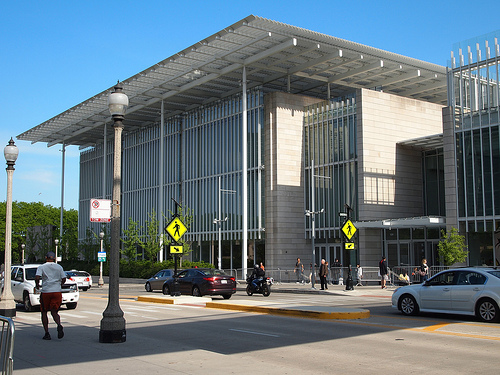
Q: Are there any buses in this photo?
A: No, there are no buses.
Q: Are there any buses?
A: No, there are no buses.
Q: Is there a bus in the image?
A: No, there are no buses.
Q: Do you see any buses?
A: No, there are no buses.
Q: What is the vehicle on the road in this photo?
A: The vehicle is a car.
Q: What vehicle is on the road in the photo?
A: The vehicle is a car.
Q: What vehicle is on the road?
A: The vehicle is a car.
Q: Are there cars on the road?
A: Yes, there is a car on the road.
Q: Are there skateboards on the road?
A: No, there is a car on the road.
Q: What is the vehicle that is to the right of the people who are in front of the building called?
A: The vehicle is a car.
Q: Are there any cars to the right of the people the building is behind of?
A: Yes, there is a car to the right of the people.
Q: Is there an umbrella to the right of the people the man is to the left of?
A: No, there is a car to the right of the people.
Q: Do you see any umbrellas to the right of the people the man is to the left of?
A: No, there is a car to the right of the people.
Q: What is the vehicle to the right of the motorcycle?
A: The vehicle is a car.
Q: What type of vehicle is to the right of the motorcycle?
A: The vehicle is a car.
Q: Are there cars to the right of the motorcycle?
A: Yes, there is a car to the right of the motorcycle.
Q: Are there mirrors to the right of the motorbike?
A: No, there is a car to the right of the motorbike.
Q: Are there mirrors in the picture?
A: No, there are no mirrors.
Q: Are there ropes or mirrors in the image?
A: No, there are no mirrors or ropes.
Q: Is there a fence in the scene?
A: Yes, there is a fence.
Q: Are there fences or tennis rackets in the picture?
A: Yes, there is a fence.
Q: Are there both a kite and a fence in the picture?
A: No, there is a fence but no kites.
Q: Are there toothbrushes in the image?
A: No, there are no toothbrushes.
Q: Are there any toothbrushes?
A: No, there are no toothbrushes.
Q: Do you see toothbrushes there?
A: No, there are no toothbrushes.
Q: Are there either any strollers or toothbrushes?
A: No, there are no toothbrushes or strollers.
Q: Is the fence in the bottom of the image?
A: Yes, the fence is in the bottom of the image.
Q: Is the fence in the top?
A: No, the fence is in the bottom of the image.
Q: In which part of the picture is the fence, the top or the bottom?
A: The fence is in the bottom of the image.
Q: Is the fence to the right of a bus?
A: No, the fence is to the right of the car.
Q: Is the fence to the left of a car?
A: No, the fence is to the right of a car.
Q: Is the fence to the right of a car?
A: Yes, the fence is to the right of a car.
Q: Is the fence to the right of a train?
A: No, the fence is to the right of a car.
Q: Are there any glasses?
A: No, there are no glasses.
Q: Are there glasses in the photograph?
A: No, there are no glasses.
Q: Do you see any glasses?
A: No, there are no glasses.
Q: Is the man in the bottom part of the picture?
A: Yes, the man is in the bottom of the image.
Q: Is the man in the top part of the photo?
A: No, the man is in the bottom of the image.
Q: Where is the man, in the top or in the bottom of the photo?
A: The man is in the bottom of the image.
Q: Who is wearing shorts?
A: The man is wearing shorts.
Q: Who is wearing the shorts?
A: The man is wearing shorts.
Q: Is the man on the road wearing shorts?
A: Yes, the man is wearing shorts.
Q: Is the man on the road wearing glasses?
A: No, the man is wearing shorts.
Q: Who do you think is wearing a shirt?
A: The man is wearing a shirt.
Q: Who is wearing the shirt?
A: The man is wearing a shirt.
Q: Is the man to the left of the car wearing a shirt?
A: Yes, the man is wearing a shirt.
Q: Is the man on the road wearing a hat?
A: No, the man is wearing a shirt.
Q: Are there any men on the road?
A: Yes, there is a man on the road.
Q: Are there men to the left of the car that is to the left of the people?
A: Yes, there is a man to the left of the car.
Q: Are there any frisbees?
A: No, there are no frisbees.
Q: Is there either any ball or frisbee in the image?
A: No, there are no frisbees or balls.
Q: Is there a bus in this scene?
A: No, there are no buses.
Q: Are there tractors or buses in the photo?
A: No, there are no buses or tractors.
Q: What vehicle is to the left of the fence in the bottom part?
A: The vehicle is a car.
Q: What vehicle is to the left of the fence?
A: The vehicle is a car.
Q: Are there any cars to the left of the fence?
A: Yes, there is a car to the left of the fence.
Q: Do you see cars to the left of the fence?
A: Yes, there is a car to the left of the fence.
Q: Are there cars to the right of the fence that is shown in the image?
A: No, the car is to the left of the fence.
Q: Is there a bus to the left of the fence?
A: No, there is a car to the left of the fence.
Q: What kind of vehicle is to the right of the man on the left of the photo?
A: The vehicle is a car.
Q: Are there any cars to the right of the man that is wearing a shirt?
A: Yes, there is a car to the right of the man.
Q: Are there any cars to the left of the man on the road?
A: No, the car is to the right of the man.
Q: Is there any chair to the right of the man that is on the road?
A: No, there is a car to the right of the man.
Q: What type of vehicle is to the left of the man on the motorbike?
A: The vehicle is a car.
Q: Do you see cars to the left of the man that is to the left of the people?
A: Yes, there is a car to the left of the man.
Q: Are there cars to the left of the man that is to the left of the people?
A: Yes, there is a car to the left of the man.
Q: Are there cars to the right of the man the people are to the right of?
A: No, the car is to the left of the man.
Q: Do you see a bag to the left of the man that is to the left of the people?
A: No, there is a car to the left of the man.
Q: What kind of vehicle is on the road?
A: The vehicle is a car.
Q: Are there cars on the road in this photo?
A: Yes, there is a car on the road.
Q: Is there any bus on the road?
A: No, there is a car on the road.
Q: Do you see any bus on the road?
A: No, there is a car on the road.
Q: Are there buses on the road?
A: No, there is a car on the road.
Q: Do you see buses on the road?
A: No, there is a car on the road.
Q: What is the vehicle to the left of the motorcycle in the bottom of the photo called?
A: The vehicle is a car.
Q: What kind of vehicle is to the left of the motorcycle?
A: The vehicle is a car.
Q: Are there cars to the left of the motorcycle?
A: Yes, there is a car to the left of the motorcycle.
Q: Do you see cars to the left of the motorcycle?
A: Yes, there is a car to the left of the motorcycle.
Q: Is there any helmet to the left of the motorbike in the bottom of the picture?
A: No, there is a car to the left of the motorbike.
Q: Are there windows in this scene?
A: Yes, there are windows.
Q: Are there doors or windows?
A: Yes, there are windows.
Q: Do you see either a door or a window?
A: Yes, there are windows.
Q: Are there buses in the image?
A: No, there are no buses.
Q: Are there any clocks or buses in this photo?
A: No, there are no buses or clocks.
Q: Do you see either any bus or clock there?
A: No, there are no buses or clocks.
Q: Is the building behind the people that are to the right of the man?
A: Yes, the building is behind the people.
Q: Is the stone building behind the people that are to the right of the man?
A: Yes, the building is behind the people.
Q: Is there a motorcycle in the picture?
A: Yes, there is a motorcycle.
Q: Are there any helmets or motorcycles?
A: Yes, there is a motorcycle.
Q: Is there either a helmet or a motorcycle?
A: Yes, there is a motorcycle.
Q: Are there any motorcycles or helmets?
A: Yes, there is a motorcycle.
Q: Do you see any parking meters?
A: No, there are no parking meters.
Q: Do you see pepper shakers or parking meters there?
A: No, there are no parking meters or pepper shakers.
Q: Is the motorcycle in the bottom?
A: Yes, the motorcycle is in the bottom of the image.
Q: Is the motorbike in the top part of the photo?
A: No, the motorbike is in the bottom of the image.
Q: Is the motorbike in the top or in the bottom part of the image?
A: The motorbike is in the bottom of the image.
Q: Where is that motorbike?
A: The motorbike is on the road.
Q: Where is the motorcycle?
A: The motorbike is on the road.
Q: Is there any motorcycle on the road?
A: Yes, there is a motorcycle on the road.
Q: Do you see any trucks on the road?
A: No, there is a motorcycle on the road.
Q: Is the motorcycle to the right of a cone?
A: No, the motorcycle is to the right of the car.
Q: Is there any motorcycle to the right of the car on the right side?
A: No, the motorcycle is to the left of the car.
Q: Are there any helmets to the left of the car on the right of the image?
A: No, there is a motorcycle to the left of the car.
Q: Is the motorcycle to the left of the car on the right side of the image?
A: Yes, the motorcycle is to the left of the car.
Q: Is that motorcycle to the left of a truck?
A: No, the motorcycle is to the left of the car.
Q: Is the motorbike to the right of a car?
A: No, the motorbike is to the left of a car.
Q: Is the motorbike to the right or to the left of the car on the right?
A: The motorbike is to the left of the car.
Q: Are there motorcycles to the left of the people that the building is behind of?
A: Yes, there is a motorcycle to the left of the people.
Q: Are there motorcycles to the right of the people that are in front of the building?
A: No, the motorcycle is to the left of the people.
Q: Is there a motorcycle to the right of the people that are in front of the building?
A: No, the motorcycle is to the left of the people.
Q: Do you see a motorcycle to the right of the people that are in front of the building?
A: No, the motorcycle is to the left of the people.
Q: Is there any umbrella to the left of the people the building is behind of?
A: No, there is a motorcycle to the left of the people.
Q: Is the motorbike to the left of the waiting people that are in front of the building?
A: Yes, the motorbike is to the left of the people.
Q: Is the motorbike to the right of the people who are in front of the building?
A: No, the motorbike is to the left of the people.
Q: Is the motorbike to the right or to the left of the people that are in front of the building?
A: The motorbike is to the left of the people.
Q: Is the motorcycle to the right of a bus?
A: No, the motorcycle is to the right of the car.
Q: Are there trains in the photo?
A: No, there are no trains.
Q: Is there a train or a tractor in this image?
A: No, there are no trains or tractors.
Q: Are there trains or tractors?
A: No, there are no trains or tractors.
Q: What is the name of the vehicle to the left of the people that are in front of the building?
A: The vehicle is a car.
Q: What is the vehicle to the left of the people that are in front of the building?
A: The vehicle is a car.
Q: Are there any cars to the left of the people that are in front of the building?
A: Yes, there is a car to the left of the people.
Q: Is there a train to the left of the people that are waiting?
A: No, there is a car to the left of the people.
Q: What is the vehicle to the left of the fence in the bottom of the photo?
A: The vehicle is a car.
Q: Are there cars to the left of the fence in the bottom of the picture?
A: Yes, there is a car to the left of the fence.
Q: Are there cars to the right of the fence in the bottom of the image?
A: No, the car is to the left of the fence.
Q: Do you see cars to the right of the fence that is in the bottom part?
A: No, the car is to the left of the fence.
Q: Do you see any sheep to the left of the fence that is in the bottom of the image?
A: No, there is a car to the left of the fence.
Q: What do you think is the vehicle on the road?
A: The vehicle is a car.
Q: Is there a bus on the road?
A: No, there is a car on the road.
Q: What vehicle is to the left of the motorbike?
A: The vehicle is a car.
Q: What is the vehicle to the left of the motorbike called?
A: The vehicle is a car.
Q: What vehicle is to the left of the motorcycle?
A: The vehicle is a car.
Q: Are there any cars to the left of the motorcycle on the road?
A: Yes, there is a car to the left of the motorcycle.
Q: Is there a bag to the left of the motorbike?
A: No, there is a car to the left of the motorbike.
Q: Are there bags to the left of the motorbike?
A: No, there is a car to the left of the motorbike.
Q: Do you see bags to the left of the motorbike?
A: No, there is a car to the left of the motorbike.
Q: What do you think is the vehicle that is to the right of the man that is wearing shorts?
A: The vehicle is a car.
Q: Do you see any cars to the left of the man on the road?
A: No, the car is to the right of the man.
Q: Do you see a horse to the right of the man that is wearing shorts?
A: No, there is a car to the right of the man.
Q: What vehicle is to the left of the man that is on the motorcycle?
A: The vehicle is a car.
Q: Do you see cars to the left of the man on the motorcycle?
A: Yes, there is a car to the left of the man.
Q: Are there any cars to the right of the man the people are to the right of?
A: No, the car is to the left of the man.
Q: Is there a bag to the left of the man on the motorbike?
A: No, there is a car to the left of the man.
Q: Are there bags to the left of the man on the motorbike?
A: No, there is a car to the left of the man.